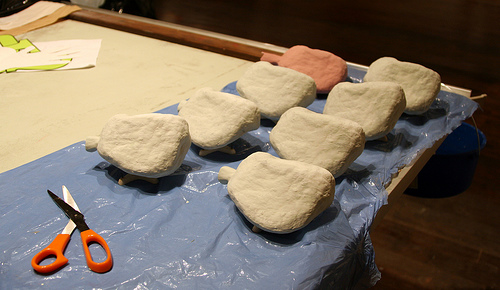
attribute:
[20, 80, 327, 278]
cloth — blue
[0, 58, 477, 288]
plastic — blue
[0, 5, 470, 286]
table top — beige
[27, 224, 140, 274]
handles — orange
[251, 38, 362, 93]
rock — pink